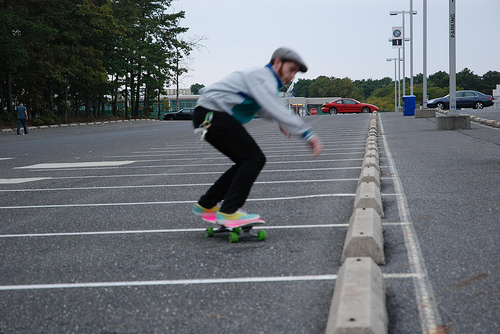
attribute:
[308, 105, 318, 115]
stop sign — red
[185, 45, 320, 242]
person — skateboarding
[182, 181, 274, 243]
shoes — colorful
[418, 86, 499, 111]
car — blue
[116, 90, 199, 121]
building — turquoise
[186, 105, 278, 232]
pants — black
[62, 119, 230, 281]
lines — white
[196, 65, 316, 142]
jacket — gray, blue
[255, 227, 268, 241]
wheel — green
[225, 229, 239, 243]
wheel — green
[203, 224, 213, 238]
wheel — green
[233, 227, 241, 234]
wheel — green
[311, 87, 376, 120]
car — red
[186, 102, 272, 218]
pants — black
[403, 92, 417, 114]
container — Blue 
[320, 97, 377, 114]
car — parked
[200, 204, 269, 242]
skateboard — pink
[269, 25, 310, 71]
hat — gray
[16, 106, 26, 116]
shirt — blue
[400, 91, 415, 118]
trashcan — blue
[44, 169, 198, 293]
paint — white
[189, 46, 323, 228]
man — leaning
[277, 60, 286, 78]
burns — big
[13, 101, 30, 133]
man — blue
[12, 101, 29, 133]
person — walking